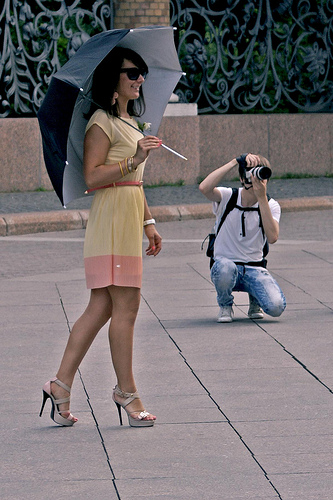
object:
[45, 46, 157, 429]
woman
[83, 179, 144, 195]
belt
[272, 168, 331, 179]
grass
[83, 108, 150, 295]
dress.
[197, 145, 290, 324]
man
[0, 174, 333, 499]
ground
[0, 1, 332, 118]
metal frame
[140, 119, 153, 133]
white flower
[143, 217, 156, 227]
band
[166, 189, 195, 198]
stones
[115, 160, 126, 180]
bracelet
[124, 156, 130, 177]
bracelet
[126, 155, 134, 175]
bracelet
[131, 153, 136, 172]
bracelet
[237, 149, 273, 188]
camera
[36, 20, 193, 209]
umbrella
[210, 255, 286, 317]
jeans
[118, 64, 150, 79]
sunglasses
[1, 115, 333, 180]
wall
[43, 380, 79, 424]
feet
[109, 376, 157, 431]
sandals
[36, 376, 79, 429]
high heels